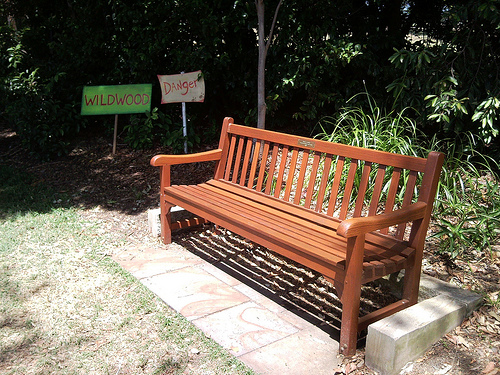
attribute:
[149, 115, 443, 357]
bench — wooden, brown, empty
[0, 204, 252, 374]
grass — dead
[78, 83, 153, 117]
sign — green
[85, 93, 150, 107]
lettering — red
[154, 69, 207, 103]
sign — white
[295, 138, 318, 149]
plaque — brass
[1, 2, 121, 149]
tree — green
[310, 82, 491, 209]
plant — green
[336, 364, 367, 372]
leaf — dried